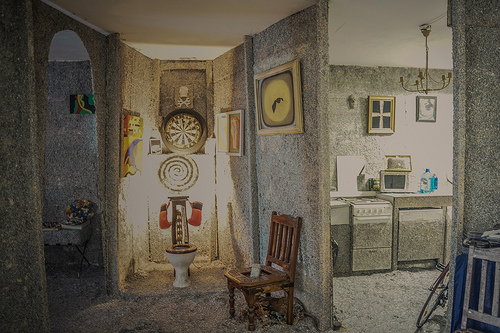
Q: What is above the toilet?
A: A dartboard.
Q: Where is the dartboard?
A: Above the toilet.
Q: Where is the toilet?
A: In the bathroom.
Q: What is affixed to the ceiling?
A: A chandelier.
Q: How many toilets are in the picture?
A: One.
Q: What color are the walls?
A: Gray.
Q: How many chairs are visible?
A: One.